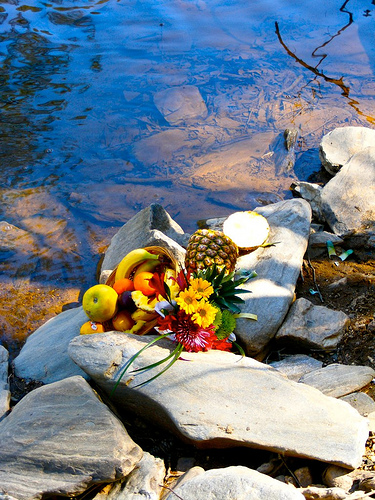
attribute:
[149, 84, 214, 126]
rock — brown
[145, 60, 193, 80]
rock — brown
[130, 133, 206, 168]
rock — brown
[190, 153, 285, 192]
rock — brown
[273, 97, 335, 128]
rock — brown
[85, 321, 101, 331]
sticker — red, white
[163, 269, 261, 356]
flower — yellow 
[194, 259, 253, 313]
fronds — green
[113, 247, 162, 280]
banana — yellow 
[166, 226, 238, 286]
pineapple — sliced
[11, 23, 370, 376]
water — dark, blue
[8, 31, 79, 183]
tree — green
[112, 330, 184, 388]
leaves — green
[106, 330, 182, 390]
foliage — green 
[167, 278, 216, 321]
sun flowers — yellow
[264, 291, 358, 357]
rock — dark, grey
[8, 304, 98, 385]
rock — dark, grey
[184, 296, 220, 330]
flower — yellow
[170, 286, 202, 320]
flower — yellow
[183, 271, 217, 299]
flower — yellow